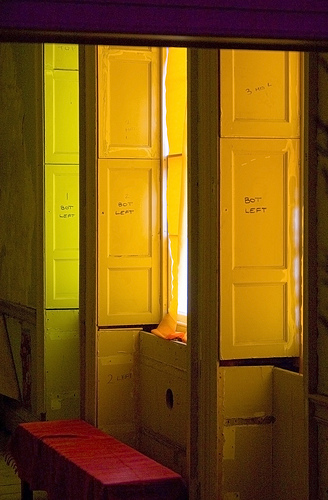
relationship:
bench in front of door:
[15, 418, 188, 499] [221, 135, 304, 358]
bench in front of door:
[15, 418, 188, 499] [96, 157, 167, 324]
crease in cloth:
[37, 428, 111, 443] [32, 428, 81, 444]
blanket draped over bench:
[6, 416, 187, 498] [19, 411, 181, 493]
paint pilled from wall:
[40, 313, 71, 418] [4, 41, 37, 407]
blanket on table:
[6, 416, 187, 493] [8, 419, 125, 476]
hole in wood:
[163, 386, 175, 412] [137, 330, 189, 480]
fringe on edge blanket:
[1, 446, 20, 477] [7, 415, 182, 499]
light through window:
[134, 166, 188, 246] [163, 46, 188, 334]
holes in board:
[218, 415, 272, 441] [217, 370, 283, 491]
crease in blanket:
[37, 428, 111, 443] [43, 418, 85, 454]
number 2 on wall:
[105, 371, 114, 385] [95, 325, 140, 451]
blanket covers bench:
[6, 416, 187, 498] [15, 418, 188, 499]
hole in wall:
[163, 386, 175, 412] [0, 299, 328, 499]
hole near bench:
[163, 386, 175, 412] [19, 404, 161, 478]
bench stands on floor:
[15, 418, 188, 499] [2, 457, 21, 499]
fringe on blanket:
[1, 446, 26, 477] [6, 416, 187, 498]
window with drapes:
[152, 45, 188, 332] [150, 45, 188, 343]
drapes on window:
[16, 45, 305, 358] [157, 45, 187, 333]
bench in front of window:
[15, 418, 188, 499] [157, 45, 187, 333]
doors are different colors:
[41, 42, 307, 498] [87, 43, 310, 499]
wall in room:
[32, 43, 302, 281] [17, 39, 311, 479]